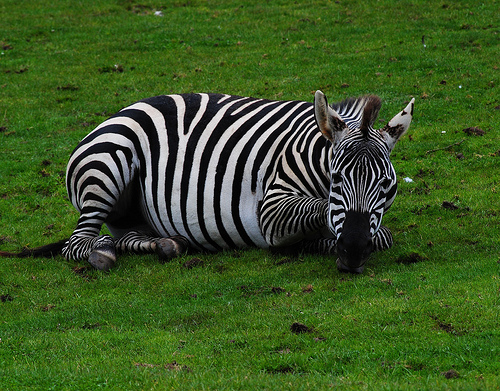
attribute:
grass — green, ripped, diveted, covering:
[188, 20, 347, 72]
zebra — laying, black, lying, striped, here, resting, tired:
[111, 88, 408, 233]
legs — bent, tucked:
[58, 192, 126, 265]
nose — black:
[349, 207, 398, 255]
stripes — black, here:
[120, 118, 285, 202]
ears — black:
[305, 98, 440, 138]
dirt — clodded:
[215, 315, 389, 346]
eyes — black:
[320, 147, 401, 202]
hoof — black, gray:
[144, 237, 208, 267]